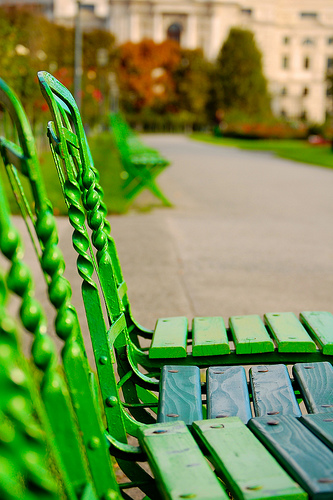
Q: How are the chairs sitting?
A: Next to each other.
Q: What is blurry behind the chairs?
A: Shrubbery.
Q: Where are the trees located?
A: Along the driveway.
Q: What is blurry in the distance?
A: Chairs.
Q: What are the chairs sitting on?
A: The sidewalk.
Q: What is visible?
A: Green chairs.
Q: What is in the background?
A: Trees.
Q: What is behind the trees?
A: A building.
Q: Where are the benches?
A: In a big garden.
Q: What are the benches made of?
A: Wood and metal.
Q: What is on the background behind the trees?
A: A beige and white huge building.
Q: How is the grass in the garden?
A: Cleanly and evenly cut.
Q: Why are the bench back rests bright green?
A: To match the color of the grass.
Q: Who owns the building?
A: It is a privately owned building.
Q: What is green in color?
A: The chairs.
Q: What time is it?
A: Afternoon.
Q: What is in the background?
A: Trees.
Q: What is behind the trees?
A: A building.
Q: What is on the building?
A: Windows.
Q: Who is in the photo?
A: No people.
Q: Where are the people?
A: None in photo.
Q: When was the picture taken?
A: During the day.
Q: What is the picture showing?
A: Chairs.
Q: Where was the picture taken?
A: In a park.